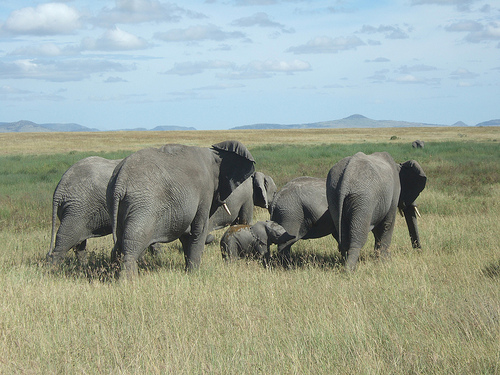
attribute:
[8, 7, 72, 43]
cloud — puffy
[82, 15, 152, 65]
cloud — puffy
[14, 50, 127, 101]
cloud — puffy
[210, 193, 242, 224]
tusks — white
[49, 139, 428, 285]
elephants — walking, gray, grey, standing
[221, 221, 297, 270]
elephant — baby, walking, young, dirty, surrounded, grey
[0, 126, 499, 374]
plain — grassy, large, tall, yellow, brown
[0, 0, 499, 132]
sky — blue, hazy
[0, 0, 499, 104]
clouds — white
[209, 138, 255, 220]
ear — sticking out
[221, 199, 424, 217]
elephant tusks — white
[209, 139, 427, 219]
ears — very large, big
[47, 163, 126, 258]
tails — long, thin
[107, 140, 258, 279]
elephant — big